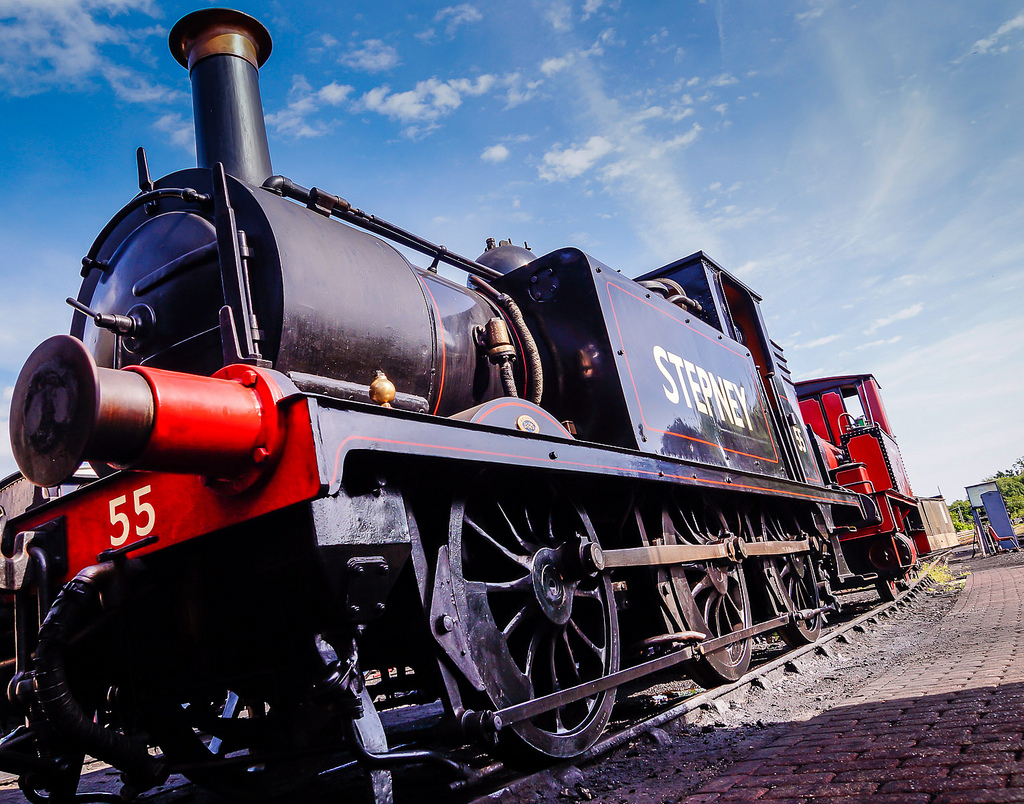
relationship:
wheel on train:
[640, 495, 764, 688] [10, 11, 966, 793]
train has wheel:
[10, 11, 966, 793] [747, 508, 841, 649]